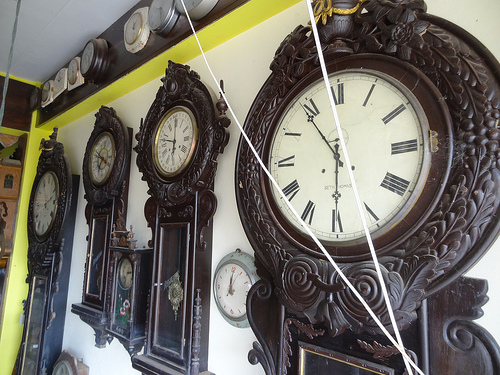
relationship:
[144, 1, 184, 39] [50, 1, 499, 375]
clock on wall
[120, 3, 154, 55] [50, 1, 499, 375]
clock on wall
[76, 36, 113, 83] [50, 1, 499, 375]
clock on wall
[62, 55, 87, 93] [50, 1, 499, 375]
clock on wall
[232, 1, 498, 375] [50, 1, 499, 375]
clock on wall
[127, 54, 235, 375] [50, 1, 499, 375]
clock on wall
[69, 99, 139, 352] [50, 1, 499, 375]
clock on wall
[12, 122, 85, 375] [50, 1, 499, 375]
clock on wall